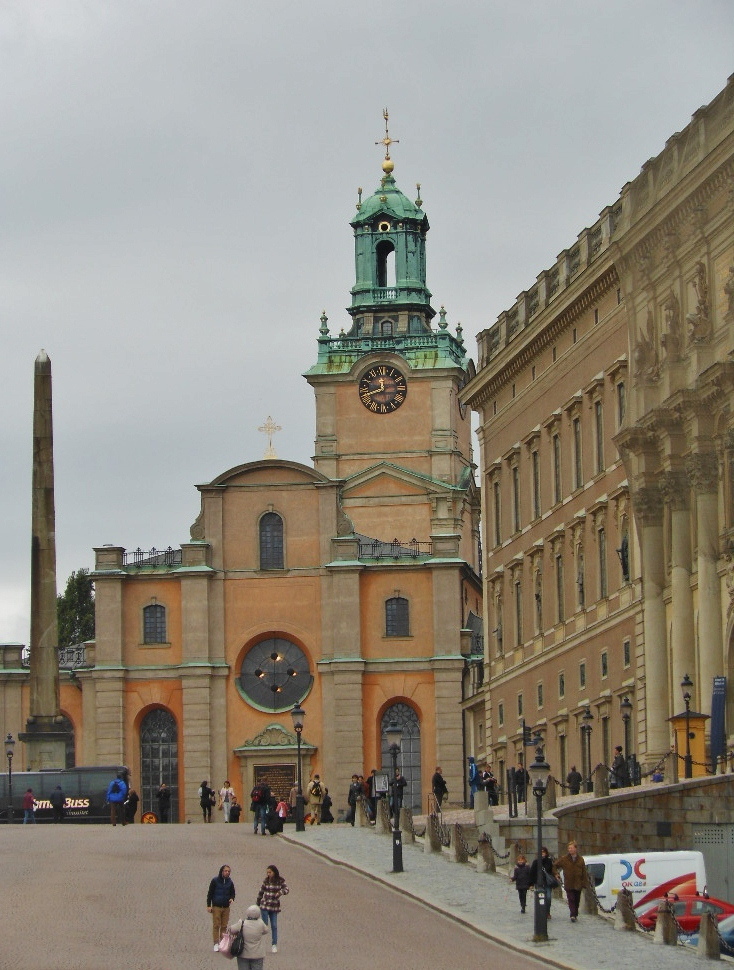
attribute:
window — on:
[379, 592, 424, 638]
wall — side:
[206, 467, 395, 617]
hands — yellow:
[366, 359, 402, 395]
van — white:
[571, 848, 709, 944]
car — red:
[646, 894, 711, 936]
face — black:
[356, 366, 410, 412]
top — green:
[299, 86, 464, 374]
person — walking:
[503, 860, 531, 904]